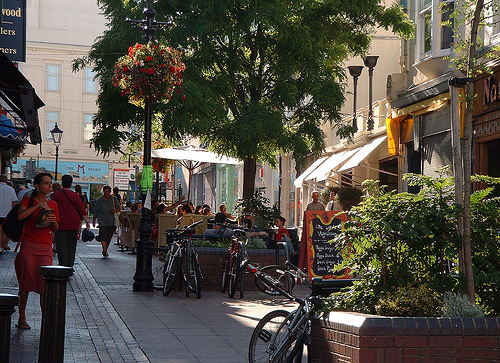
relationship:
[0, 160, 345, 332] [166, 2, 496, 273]
people walking near shops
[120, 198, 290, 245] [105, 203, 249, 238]
people sitting at tables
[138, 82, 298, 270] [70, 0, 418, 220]
tables underneath tree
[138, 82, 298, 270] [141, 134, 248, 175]
tables underneath umbrellas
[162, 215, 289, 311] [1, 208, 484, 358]
planters centered in area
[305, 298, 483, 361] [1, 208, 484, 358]
planter centered in area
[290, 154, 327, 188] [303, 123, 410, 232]
awning hanging above store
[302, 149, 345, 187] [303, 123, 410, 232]
awning hanging above store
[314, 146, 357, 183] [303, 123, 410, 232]
awning hanging above store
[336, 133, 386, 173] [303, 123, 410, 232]
awning hanging above store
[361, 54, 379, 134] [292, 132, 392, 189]
sconces sitting above awnings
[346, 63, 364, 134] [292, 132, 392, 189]
sconces sitting above awnings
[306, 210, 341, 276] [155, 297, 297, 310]
poster board sitting on top of sidewalk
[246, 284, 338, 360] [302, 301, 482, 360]
bicycle leaning against step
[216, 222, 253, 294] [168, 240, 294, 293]
bicycle leaning against step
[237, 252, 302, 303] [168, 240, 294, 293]
bicycle leaning against step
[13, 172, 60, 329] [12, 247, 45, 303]
woman wearing skirt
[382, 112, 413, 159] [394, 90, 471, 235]
flag hanging from store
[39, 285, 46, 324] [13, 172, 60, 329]
leg attached to woman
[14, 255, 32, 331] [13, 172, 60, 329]
leg attached to woman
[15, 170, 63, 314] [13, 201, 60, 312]
woman wearing a dress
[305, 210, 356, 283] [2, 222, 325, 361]
poster board standing on sidewalk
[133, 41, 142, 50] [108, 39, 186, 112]
flower on plant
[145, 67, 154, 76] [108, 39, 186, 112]
flower on plant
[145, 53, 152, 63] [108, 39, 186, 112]
flower on plant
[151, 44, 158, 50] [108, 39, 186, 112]
flower on plant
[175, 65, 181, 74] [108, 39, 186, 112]
flower on plant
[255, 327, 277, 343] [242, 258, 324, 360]
pedal on bike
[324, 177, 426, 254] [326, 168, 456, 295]
leaves on plant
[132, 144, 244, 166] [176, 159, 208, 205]
umbrella on pole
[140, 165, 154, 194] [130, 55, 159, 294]
poster on a pole